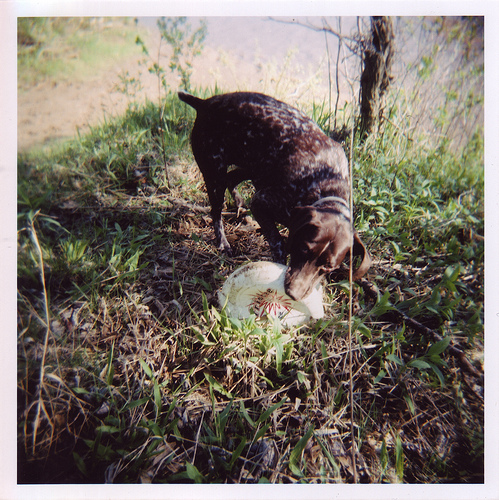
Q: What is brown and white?
A: The fur.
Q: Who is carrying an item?
A: The dog.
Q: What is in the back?
A: A tree.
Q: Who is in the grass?
A: A brown dog.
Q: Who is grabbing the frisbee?
A: The dog.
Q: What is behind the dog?
A: A tree.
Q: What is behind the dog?
A: A path.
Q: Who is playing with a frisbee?
A: A dog.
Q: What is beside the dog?
A: Tall weeds.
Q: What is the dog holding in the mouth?
A: Frisbee.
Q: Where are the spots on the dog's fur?
A: On the back.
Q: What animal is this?
A: Dog.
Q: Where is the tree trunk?
A: Behind the dog.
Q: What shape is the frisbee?
A: Round.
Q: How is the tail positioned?
A: Sticking up.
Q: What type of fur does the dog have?
A: Short and brown.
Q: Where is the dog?
A: The dog is outside.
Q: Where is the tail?
A: On the back of the dog.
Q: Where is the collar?
A: On the neck.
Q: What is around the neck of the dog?
A: The collar.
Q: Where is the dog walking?
A: In the tall weeds and grass.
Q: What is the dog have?
A: A frisbee.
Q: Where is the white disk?
A: In the dog's mouth.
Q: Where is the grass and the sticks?
A: Under the dog.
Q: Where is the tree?
A: Behind the dog.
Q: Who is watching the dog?
A: People.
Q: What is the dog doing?
A: Getting the frisbee.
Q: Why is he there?
A: Getting the frisbee.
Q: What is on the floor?
A: The frisbee.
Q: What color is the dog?
A: Brown.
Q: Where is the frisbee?
A: On the ground.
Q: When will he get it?
A: Now.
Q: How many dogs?
A: 1.